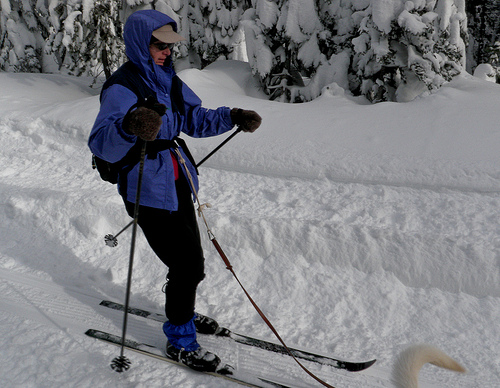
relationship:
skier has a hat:
[86, 9, 260, 368] [153, 25, 182, 44]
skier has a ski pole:
[86, 9, 260, 368] [102, 128, 240, 245]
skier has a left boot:
[86, 9, 260, 368] [168, 341, 215, 371]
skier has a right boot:
[86, 9, 260, 368] [193, 311, 218, 334]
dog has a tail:
[394, 344, 499, 385] [393, 343, 464, 386]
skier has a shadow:
[86, 9, 260, 368] [3, 187, 169, 354]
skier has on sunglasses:
[86, 9, 260, 368] [152, 40, 175, 50]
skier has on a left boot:
[86, 9, 260, 368] [186, 313, 221, 336]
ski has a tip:
[98, 298, 376, 371] [346, 357, 376, 373]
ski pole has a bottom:
[102, 128, 240, 245] [103, 232, 118, 249]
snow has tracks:
[2, 69, 499, 387] [23, 118, 110, 172]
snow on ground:
[2, 69, 499, 387] [3, 68, 497, 387]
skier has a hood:
[86, 9, 260, 368] [124, 10, 177, 72]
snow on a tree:
[2, 69, 499, 387] [243, 0, 469, 103]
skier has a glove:
[86, 9, 260, 368] [229, 107, 262, 132]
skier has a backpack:
[86, 9, 260, 368] [93, 59, 183, 180]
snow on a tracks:
[2, 69, 499, 387] [23, 118, 110, 172]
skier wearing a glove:
[86, 9, 260, 368] [229, 107, 262, 132]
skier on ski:
[86, 9, 260, 368] [98, 298, 376, 371]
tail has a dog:
[393, 343, 464, 386] [394, 344, 499, 385]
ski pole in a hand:
[102, 128, 240, 245] [232, 107, 261, 134]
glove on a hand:
[229, 107, 262, 132] [232, 107, 261, 134]